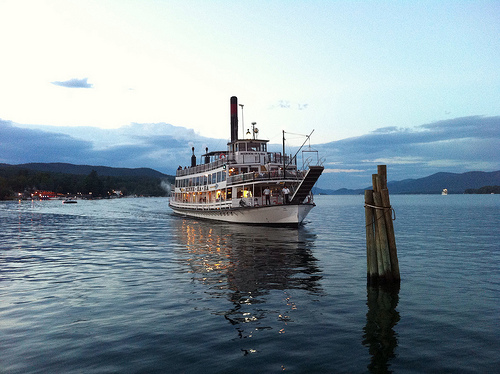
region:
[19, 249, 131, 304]
calm blue waters in the river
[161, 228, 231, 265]
boat's reflection in the water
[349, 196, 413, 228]
string around wood post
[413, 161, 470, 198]
tall mountain range in the far distance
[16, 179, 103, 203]
houses on the shore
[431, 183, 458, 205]
white object far away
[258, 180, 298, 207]
people standing on the boat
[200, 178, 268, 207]
light in the boat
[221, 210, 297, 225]
white paint on the side of boat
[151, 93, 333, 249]
large passenger boat in the water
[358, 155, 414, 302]
THE POSTS ARE WOODEN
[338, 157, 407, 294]
THE POSTS ARE STICKING OUT OF THE WATER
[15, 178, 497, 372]
THE WATER IS CALM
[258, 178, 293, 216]
THE MEN ARE ON THE BOAT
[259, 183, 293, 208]
THE MEN ARE WEARING WHITE SHIRTS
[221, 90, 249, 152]
THE BOAT HAS A TALL STACK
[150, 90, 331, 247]
THE BOAT IS WHITE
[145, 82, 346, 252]
THE BOAT IS IN THE WATER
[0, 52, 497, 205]
THE SKY HAS FLUFFY WHITE CLOUDS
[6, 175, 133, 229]
THE BUILDINGS AND HOUSES DOT THE SHORELINE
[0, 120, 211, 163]
some white and black clouds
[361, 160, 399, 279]
a bunch of wooden post in the water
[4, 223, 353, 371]
a patch of water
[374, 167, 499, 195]
hazy dark mountains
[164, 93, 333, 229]
a white triple decker boat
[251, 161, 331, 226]
the front of a boat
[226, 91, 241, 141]
a boat smoke stack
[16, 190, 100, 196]
lights that are turned on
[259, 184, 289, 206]
people standing on a boat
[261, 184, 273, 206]
a guy in a white shirt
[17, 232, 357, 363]
The water on the lake is calm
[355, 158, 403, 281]
A bundle of wooden sticks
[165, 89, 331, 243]
A cruise ferry floating by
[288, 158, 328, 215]
The stairs on the ferry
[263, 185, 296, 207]
Crew members on the ferry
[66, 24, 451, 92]
The sun has set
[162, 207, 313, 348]
The reflection of the ferry on the water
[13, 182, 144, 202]
The land and docking station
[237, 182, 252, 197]
The lights are on in the ferry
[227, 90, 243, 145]
The steam pipe on the ferry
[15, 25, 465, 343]
large ship in calm water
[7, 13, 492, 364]
boat moving on calm water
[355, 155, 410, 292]
wooden marker jutting out of water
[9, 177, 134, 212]
boats and buildings along the shoreline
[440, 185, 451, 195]
white boat in the distance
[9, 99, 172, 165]
dark clouds in a partly cloudy sky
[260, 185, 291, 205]
men working on boat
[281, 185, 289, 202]
man wearing a uniform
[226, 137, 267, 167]
captains cabin on the boat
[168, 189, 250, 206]
lights on the exterior of the ship